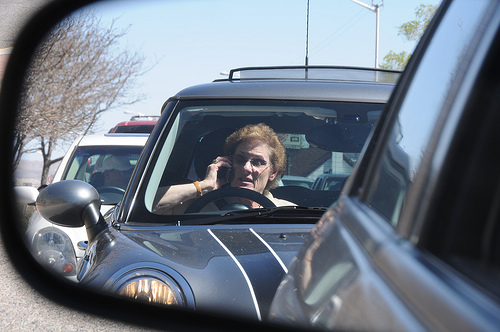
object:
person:
[168, 120, 320, 220]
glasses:
[231, 150, 266, 170]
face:
[225, 147, 279, 191]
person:
[175, 129, 324, 220]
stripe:
[207, 226, 298, 325]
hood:
[88, 201, 334, 313]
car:
[83, 65, 458, 326]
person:
[94, 149, 138, 200]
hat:
[98, 152, 138, 175]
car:
[21, 128, 152, 283]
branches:
[40, 25, 151, 158]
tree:
[28, 27, 145, 184]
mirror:
[53, 9, 418, 329]